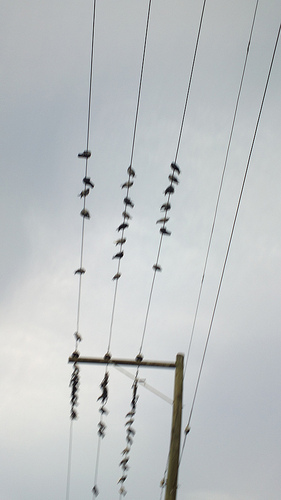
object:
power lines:
[65, 0, 281, 500]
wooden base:
[68, 353, 185, 499]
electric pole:
[67, 352, 185, 500]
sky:
[0, 0, 279, 494]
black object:
[72, 350, 79, 358]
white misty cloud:
[10, 182, 63, 358]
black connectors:
[72, 351, 143, 362]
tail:
[78, 153, 84, 158]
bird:
[74, 149, 95, 276]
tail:
[89, 182, 94, 188]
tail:
[165, 230, 173, 236]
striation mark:
[115, 363, 174, 406]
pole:
[164, 354, 184, 500]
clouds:
[23, 39, 238, 157]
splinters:
[177, 393, 181, 401]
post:
[68, 352, 184, 500]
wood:
[164, 353, 184, 500]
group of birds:
[74, 147, 181, 281]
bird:
[112, 167, 136, 281]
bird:
[74, 331, 82, 342]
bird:
[152, 162, 180, 272]